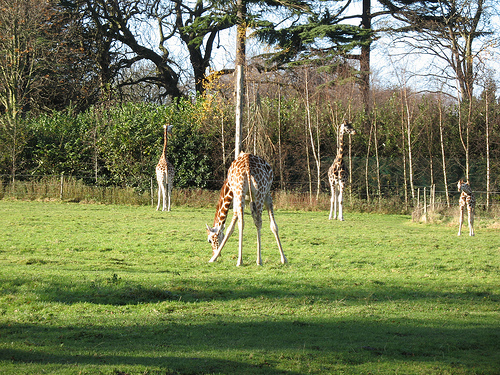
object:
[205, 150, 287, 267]
giraffe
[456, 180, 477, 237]
giraffe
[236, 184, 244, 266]
leg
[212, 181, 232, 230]
neck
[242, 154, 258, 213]
tail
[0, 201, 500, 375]
grass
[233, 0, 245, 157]
pole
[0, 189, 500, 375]
field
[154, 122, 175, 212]
giraffes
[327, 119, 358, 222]
giraffe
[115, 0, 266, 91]
trees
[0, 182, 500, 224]
fence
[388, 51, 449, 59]
branch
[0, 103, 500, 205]
shrubs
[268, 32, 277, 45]
leaves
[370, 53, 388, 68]
skies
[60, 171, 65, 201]
poles